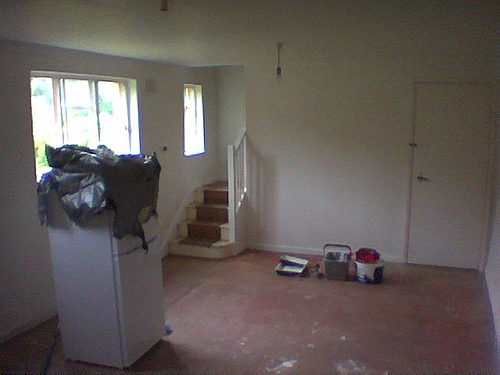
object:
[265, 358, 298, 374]
powder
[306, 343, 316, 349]
powder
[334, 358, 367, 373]
powder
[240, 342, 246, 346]
powder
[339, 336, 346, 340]
powder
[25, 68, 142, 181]
frame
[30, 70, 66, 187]
window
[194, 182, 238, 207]
steps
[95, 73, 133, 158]
window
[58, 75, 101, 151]
window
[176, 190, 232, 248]
brown rug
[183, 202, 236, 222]
steps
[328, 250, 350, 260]
paint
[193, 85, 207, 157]
windows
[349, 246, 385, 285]
bucket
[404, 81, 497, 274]
door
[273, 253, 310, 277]
paint tray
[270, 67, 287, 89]
light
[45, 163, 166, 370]
fridge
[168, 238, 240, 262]
steps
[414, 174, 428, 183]
door knob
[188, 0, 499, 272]
wall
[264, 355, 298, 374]
paint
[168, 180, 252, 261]
staircase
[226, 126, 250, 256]
rail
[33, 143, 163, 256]
cover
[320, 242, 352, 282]
pail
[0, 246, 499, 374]
floor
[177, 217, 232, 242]
steps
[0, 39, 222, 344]
wall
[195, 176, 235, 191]
next floor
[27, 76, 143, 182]
sun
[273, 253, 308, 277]
brush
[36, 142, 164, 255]
plasic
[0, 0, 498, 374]
room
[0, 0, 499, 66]
ceiling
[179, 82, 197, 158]
window